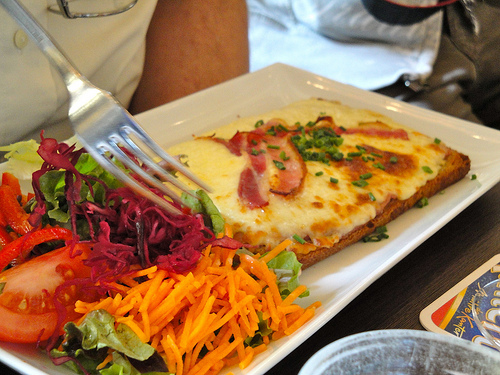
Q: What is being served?
A: A cheese dish.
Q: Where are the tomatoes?
A: On the left of the plate.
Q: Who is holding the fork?
A: The person eating.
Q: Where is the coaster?
A: In front of the plate.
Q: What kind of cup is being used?
A: Plastic.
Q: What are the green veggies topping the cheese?
A: Scallions.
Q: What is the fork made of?
A: Metal.